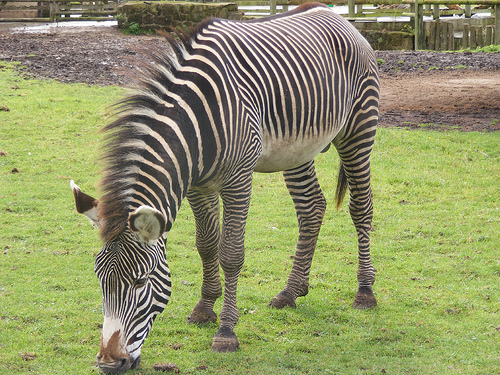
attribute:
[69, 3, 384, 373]
zebra — standing, eating, hungry, black, white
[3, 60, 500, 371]
grass — green, short, lush, long, for feeding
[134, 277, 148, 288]
eye — black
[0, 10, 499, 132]
dirt — brown, black, rocky, dirty, muddy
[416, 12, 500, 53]
fence — wooden, brown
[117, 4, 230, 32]
bushes — green